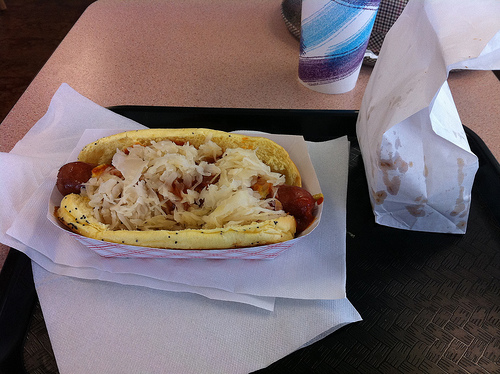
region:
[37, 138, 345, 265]
A hot dog in a plate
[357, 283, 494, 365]
The table is woven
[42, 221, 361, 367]
Napkins underneath the hot dog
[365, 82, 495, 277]
Grease coming through bag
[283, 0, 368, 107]
A paper cup on the table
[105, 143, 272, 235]
Sour kraut on the hot dog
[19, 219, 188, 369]
Stack of white napkins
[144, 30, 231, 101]
Table is brown and speckled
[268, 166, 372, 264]
Hot dog is cooked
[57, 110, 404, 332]
Bun has poppy seeds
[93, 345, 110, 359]
Small part of white napkin on table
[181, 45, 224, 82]
Small part of tan table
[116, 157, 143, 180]
One of the onions on the hot dog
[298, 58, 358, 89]
Bottom part of white, blue, and purple cup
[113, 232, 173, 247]
Bun used for the hot dog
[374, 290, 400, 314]
Small part of the black tray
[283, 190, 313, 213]
Right end of the hot dog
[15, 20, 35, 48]
Small part of brown floor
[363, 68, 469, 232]
Greasy white bag on tray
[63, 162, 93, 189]
Left end of hot dog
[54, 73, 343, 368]
a white tissue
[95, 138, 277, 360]
a white tissue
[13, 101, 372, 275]
A hot dog in basket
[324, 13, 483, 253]
A white bag with grease spots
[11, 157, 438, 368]
White napkin under hotdog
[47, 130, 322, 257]
A hotdog with sour kraut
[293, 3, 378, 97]
A cup with blue and purple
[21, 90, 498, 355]
A black carrying tray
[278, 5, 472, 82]
A mans hat by the cup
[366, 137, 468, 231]
Grease spots on bag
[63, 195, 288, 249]
Black poppy seeds on bun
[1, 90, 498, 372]
A black tray on white table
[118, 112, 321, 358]
the tissue is white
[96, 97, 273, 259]
the tissue is white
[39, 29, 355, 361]
the tissue is white